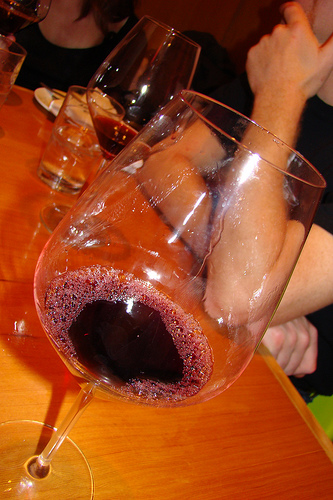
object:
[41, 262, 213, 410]
wine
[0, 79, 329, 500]
glass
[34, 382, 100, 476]
stem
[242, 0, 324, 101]
hand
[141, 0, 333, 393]
person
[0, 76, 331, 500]
table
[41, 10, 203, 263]
wineglass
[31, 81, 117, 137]
plate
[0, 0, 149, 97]
top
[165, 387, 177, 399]
bubbles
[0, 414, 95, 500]
base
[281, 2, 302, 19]
knuckle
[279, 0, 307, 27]
finger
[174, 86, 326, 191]
mouth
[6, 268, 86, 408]
shadow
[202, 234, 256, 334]
elbow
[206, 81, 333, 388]
shirt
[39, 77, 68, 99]
knife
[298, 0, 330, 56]
face